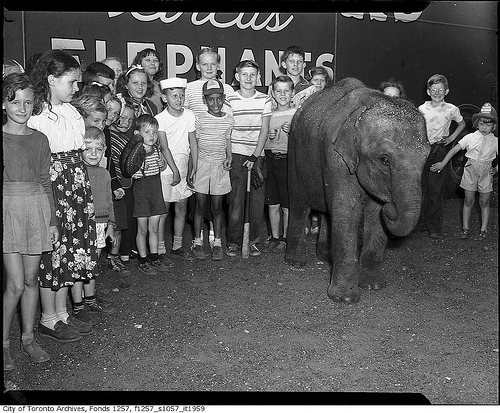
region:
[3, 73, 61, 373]
child standing next to child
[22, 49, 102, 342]
child standing next to child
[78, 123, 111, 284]
child standing next to child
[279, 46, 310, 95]
child standing next to child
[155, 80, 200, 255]
child standing next to child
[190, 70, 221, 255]
child standing next to child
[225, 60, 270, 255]
child standing next to child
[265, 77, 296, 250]
child standing next to child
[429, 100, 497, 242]
child standing next to child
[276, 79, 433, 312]
Baby elephant that is surrounded by children.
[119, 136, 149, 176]
Baseball mitt held by child.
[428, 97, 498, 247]
Little girl wearing firefighter hat.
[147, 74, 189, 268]
Little boy wearing sailors hat.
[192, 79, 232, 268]
Little boy wearing baseball cap.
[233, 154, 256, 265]
Baseball bat being held by boy.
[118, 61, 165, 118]
Little girl wearing white headband.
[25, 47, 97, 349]
Girl wearing white shirt and dark skirt with flowers on it.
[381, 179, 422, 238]
Trunk of small elephant.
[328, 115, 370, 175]
Ear of small elephant.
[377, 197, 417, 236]
grey elephant trunk turned under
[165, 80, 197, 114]
child with white sailor cap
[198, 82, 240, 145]
child with multistriped baseball cap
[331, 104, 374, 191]
ear on left of elephant's head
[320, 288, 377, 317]
dark toe nails on foot of elephants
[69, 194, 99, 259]
flowered pattern on child's dress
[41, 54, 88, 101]
dark haired girl looking at elephant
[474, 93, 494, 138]
child with fireman's hat on head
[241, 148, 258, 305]
dark wooden bat in boy's hand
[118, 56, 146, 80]
girl with white bow on head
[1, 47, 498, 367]
several children posing with an elephant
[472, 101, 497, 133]
girl is wearing a fireman-style helmet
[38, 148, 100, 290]
girl is wearing a dark skirt with a floral print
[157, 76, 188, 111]
white, sailor-type hat on boy's head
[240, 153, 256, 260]
boy holding a baseball bat by its smaller end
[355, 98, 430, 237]
elephant is curling its trunk inward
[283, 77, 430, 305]
elephant appears to be an adolescent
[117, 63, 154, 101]
girl is wearing a light headband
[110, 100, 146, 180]
boy is holding a baseball glove that appears too large for him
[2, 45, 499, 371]
dress and hairstyles of the children suggest that the image is several decades old